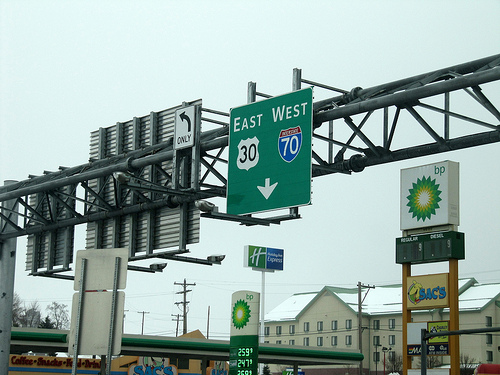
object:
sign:
[226, 86, 314, 217]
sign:
[172, 104, 195, 149]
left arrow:
[178, 109, 191, 132]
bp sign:
[228, 289, 260, 374]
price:
[236, 347, 254, 358]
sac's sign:
[404, 273, 447, 310]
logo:
[407, 281, 445, 304]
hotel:
[259, 276, 498, 375]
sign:
[243, 244, 284, 273]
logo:
[230, 299, 251, 330]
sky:
[1, 1, 498, 342]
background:
[230, 290, 259, 336]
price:
[237, 358, 252, 367]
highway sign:
[84, 99, 225, 273]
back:
[86, 97, 202, 252]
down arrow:
[254, 177, 277, 202]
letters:
[10, 353, 103, 370]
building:
[10, 329, 228, 375]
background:
[228, 335, 259, 374]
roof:
[260, 277, 499, 323]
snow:
[264, 291, 319, 322]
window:
[330, 319, 338, 333]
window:
[316, 321, 324, 332]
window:
[302, 320, 310, 333]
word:
[232, 114, 264, 133]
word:
[270, 101, 308, 122]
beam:
[0, 52, 497, 242]